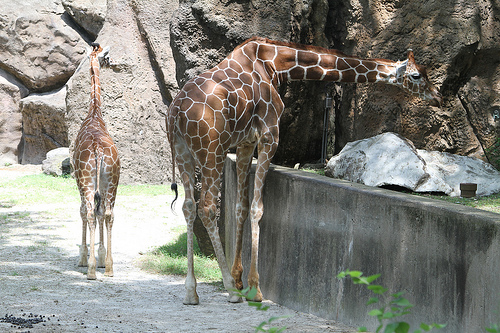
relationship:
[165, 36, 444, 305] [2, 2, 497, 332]
giraffe in pen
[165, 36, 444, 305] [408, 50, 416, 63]
giraffe has horn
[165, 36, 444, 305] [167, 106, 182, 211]
giraffe has tail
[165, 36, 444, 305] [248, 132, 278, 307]
giraffe has leg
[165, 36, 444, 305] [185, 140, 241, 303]
giraffe has leg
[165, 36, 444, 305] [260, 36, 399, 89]
giraffe has neck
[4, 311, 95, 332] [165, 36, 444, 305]
turds are from giraffe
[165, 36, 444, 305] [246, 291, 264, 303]
giraffe has foot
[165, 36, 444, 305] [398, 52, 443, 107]
giraffe has head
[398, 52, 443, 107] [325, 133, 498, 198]
head near stone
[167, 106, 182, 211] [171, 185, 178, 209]
tail has hair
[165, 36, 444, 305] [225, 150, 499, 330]
giraffe near wall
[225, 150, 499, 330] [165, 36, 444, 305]
wall behind giraffe